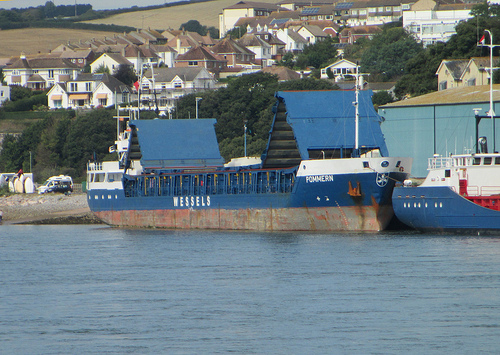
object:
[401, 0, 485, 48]
building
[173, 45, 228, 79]
house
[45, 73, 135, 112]
building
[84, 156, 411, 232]
boat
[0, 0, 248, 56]
hill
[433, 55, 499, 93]
houses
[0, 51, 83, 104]
house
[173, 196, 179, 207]
w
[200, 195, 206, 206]
letter l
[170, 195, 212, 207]
wessels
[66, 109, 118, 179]
tree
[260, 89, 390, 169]
blueroof building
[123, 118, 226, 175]
blueroof building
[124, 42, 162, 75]
house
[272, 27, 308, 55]
house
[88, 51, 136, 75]
house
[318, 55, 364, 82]
house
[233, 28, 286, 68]
house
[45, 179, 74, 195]
cars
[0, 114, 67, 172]
trees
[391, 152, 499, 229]
boat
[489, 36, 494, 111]
pole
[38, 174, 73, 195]
sedan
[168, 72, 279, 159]
trees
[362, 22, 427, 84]
tree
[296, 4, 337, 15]
roof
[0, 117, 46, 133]
overhangs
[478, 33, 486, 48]
flag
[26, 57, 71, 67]
roofs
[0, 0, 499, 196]
land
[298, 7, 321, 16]
solar panel